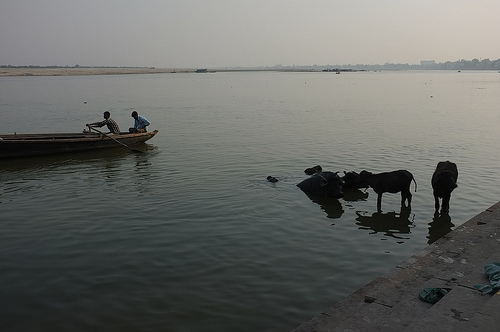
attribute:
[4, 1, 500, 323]
water — calm, blue, green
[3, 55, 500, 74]
line — small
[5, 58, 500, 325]
waters — calm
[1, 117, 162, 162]
boat — small, long, narrow, wooden, row, brown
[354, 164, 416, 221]
cow — dipping, swimming, reflected, baby, looking, small, black, drinking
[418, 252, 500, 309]
cluster — large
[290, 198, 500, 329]
cluster — rocks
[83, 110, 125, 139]
man — sitting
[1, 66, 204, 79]
land — large, sandy, brown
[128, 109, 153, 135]
man — sitting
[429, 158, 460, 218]
cow — dipping, black, small, drinking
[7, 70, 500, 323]
river — flat, grey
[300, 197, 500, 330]
steps — cement, grey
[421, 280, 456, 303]
sandals — pair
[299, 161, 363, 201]
trash — floating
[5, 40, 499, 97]
view — city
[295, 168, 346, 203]
cow — adult, drinking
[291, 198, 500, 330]
wall — retaining, cement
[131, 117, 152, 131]
shirt — blue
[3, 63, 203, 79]
shore — opposite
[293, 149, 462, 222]
group — cows, drinking